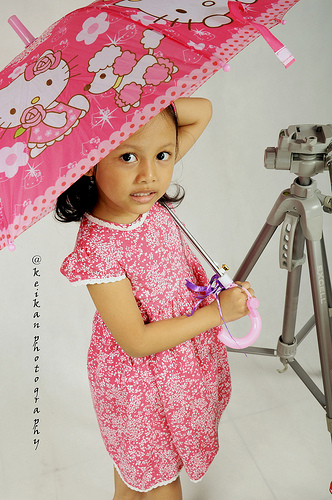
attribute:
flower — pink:
[124, 414, 145, 436]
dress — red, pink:
[61, 214, 231, 492]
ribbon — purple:
[185, 273, 223, 317]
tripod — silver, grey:
[266, 124, 331, 498]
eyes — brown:
[120, 152, 139, 164]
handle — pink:
[219, 291, 263, 351]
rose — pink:
[19, 104, 47, 129]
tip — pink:
[6, 13, 34, 47]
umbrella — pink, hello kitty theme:
[2, 1, 297, 98]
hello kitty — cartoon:
[0, 50, 89, 155]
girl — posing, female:
[61, 96, 255, 499]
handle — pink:
[220, 284, 263, 349]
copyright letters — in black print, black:
[31, 255, 44, 452]